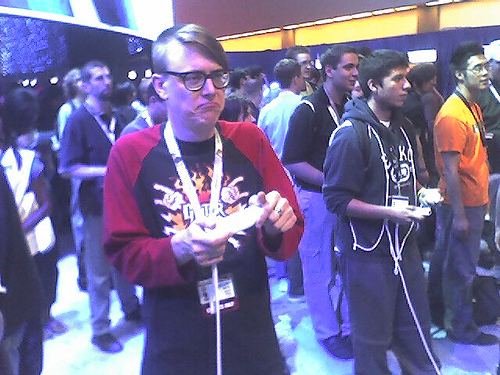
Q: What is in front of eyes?
A: Glasses.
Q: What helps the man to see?
A: Eyeglasses.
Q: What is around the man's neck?
A: A name tag.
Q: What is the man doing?
A: Playing a game.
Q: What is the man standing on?
A: The floor.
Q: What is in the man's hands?
A: A game controller.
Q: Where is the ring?
A: On the man's finger.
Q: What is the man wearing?
A: A long-sleeved t-shirt.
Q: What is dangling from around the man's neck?
A: A tag.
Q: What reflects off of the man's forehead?
A: Light.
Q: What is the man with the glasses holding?
A: A video game controller.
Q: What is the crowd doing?
A: Playing video games.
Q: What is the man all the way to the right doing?
A: Watching the other people play video games.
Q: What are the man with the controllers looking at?
A: A television where the game is being played out.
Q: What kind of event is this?
A: A video gaming event held indoors.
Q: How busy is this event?
A: This event looks busy with the crowd of people either watching or playing video games.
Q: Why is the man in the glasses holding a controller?
A: Because he is playing a video game.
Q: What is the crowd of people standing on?
A: They are standing on the floor of the building.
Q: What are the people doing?
A: Playing games.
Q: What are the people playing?
A: Video games.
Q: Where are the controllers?
A: In the people's hands.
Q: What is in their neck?
A: Tag.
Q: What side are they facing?
A: Different directions.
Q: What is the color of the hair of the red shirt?
A: Blonde.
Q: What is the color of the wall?
A: Blue and yellow.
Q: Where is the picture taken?
A: At a gaming convention.